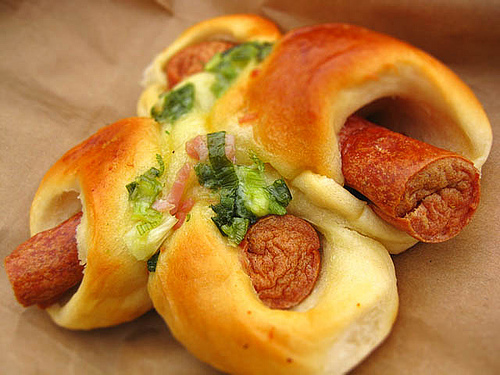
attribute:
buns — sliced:
[241, 21, 492, 131]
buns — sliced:
[73, 88, 252, 373]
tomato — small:
[166, 135, 233, 227]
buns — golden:
[28, 11, 494, 373]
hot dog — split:
[336, 115, 481, 245]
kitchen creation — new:
[4, 11, 496, 368]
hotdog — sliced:
[338, 122, 495, 254]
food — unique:
[5, 13, 494, 373]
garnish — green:
[103, 125, 291, 236]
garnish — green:
[135, 127, 296, 239]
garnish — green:
[206, 41, 273, 89]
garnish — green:
[149, 78, 196, 121]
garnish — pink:
[128, 152, 266, 243]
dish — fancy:
[3, 5, 493, 372]